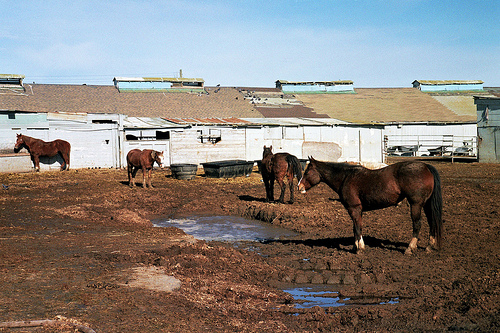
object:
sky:
[0, 1, 500, 88]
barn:
[0, 69, 499, 175]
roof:
[0, 73, 500, 124]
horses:
[14, 133, 71, 174]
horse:
[297, 155, 443, 256]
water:
[153, 212, 301, 242]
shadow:
[259, 234, 427, 254]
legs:
[340, 184, 363, 231]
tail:
[422, 163, 444, 249]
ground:
[0, 258, 500, 333]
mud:
[269, 264, 382, 289]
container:
[199, 160, 254, 178]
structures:
[0, 71, 499, 173]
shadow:
[416, 158, 479, 163]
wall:
[476, 99, 500, 164]